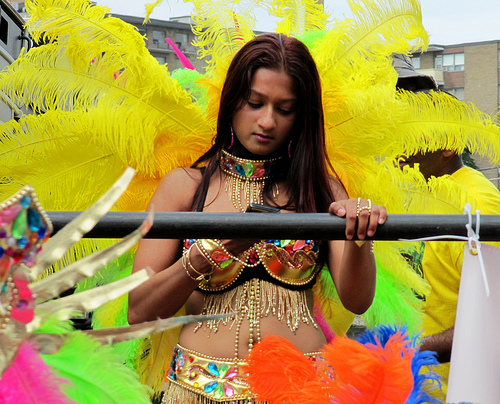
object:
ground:
[348, 160, 458, 255]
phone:
[246, 202, 280, 213]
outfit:
[0, 0, 496, 399]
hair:
[187, 32, 349, 216]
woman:
[125, 32, 382, 404]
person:
[389, 87, 500, 402]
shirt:
[397, 164, 499, 402]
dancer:
[104, 28, 441, 402]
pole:
[42, 207, 497, 246]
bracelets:
[180, 240, 234, 281]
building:
[109, 12, 497, 113]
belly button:
[248, 338, 261, 351]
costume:
[160, 147, 338, 403]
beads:
[192, 276, 318, 359]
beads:
[221, 166, 282, 212]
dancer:
[126, 29, 386, 401]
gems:
[219, 149, 290, 183]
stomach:
[180, 225, 322, 305]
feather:
[0, 0, 499, 404]